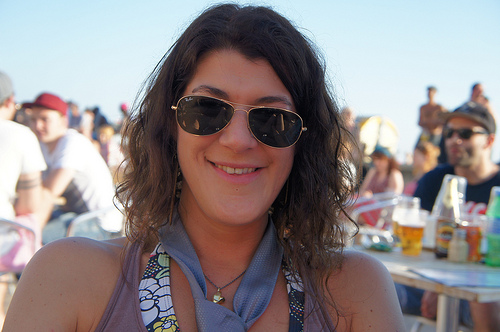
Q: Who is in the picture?
A: A woman.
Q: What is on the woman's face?
A: Glasses.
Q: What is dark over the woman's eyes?
A: Sunglasses.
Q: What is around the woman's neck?
A: Necktie.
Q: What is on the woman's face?
A: Sunglasses.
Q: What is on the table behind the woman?
A: Beer.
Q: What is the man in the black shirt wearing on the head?
A: A hat and sunglasses.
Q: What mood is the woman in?
A: Happy.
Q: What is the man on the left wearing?
A: A red hat.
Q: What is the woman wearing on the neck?
A: A necklace.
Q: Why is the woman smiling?
A: For a photo.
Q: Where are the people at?
A: An outdoor area.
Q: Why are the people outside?
A: To hang out.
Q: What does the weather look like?
A: Clear.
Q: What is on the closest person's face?
A: Sunglasses.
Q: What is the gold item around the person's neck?
A: Necklace.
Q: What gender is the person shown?
A: Female.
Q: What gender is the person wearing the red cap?
A: Male.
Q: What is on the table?
A: Drinks.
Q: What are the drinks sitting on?
A: Table.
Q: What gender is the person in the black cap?
A: Male.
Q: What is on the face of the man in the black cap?
A: Sunglasses.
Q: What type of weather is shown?
A: Clear.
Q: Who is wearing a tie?
A: Woman closest to the camera.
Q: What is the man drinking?
A: The man is drinking beer.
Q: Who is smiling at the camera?
A: A woman is smiling.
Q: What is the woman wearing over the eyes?
A: The woman is wearing sunglasses.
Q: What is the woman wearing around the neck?
A: A necktie is around the woman's neck.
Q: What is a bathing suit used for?
A: For swimming and suntanning.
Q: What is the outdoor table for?
A: For placing items on.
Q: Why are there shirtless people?
A: They are enjoying a sunny day.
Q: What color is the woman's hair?
A: Brown.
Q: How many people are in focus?
A: One.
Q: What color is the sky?
A: Blue.